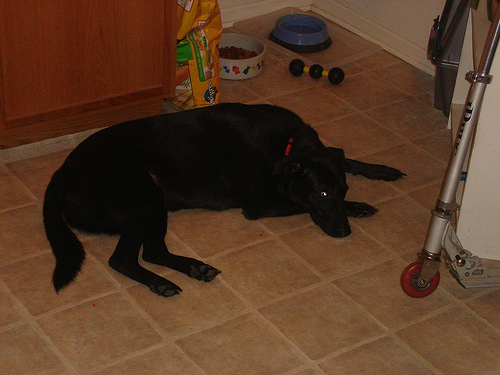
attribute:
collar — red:
[282, 130, 299, 162]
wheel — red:
[398, 262, 440, 300]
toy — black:
[285, 57, 345, 87]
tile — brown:
[257, 281, 390, 368]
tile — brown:
[390, 303, 498, 373]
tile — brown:
[202, 238, 324, 309]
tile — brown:
[166, 209, 276, 264]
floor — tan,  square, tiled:
[223, 261, 403, 363]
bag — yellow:
[173, 0, 223, 110]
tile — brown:
[30, 287, 167, 374]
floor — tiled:
[1, 4, 496, 374]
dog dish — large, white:
[224, 30, 266, 83]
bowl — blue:
[259, 6, 352, 58]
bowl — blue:
[274, 9, 335, 55]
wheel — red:
[403, 261, 443, 297]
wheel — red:
[399, 258, 441, 298]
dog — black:
[38, 101, 408, 301]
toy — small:
[282, 46, 332, 77]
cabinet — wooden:
[4, 6, 186, 147]